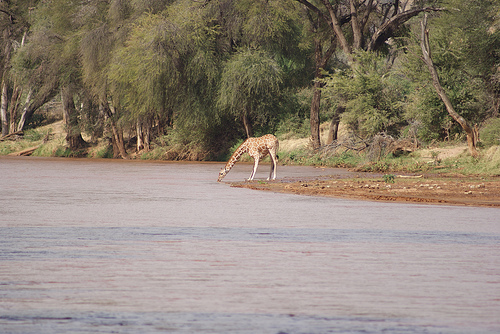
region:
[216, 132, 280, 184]
giraffe drinking at lake edge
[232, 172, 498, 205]
muddy and sandy lake shoreline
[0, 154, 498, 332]
large water source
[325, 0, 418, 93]
tree trunk of very large tree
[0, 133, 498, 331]
solitary giraffe at lake shore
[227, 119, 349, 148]
brown hillside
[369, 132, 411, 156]
large tree stump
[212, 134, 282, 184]
giraffe bends neck down to drink from lake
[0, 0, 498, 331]
giraffe drinking from lake in natural habitat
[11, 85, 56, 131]
that is a tree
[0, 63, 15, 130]
that is a tree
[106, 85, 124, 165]
that is a tree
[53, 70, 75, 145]
that is a tree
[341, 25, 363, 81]
that is a tree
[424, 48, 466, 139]
that is a tree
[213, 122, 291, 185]
that is a giraffe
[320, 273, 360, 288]
this is clean water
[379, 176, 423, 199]
that is a mudy ground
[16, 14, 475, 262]
a giraffe is taking a drink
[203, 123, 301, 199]
this giraffe's neck is bent over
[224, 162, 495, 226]
this is dirt by the water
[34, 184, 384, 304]
the water is light blue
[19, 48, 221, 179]
trees on the shore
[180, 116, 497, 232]
the giraffe is by itself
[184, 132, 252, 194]
the giraffe has a long neck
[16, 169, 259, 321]
the water looks calm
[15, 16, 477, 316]
a scene of a giraffe in the wild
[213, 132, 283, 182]
Giraffe drinking from water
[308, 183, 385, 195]
Dirt area near lake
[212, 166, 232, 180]
Head of spotted giraffe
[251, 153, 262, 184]
Leg of spotted giraffe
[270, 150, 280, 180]
Leg of spotted giraffe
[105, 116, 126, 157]
Tree trunk near edge of water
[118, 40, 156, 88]
Green tree near water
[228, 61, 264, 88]
Green tree near water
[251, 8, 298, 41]
Part of tree near water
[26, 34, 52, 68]
Part of tree near water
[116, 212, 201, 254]
beautiful drinking pond water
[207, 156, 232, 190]
giraffe head looking down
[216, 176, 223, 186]
giraffe mouth in water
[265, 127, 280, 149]
butt of long giraffe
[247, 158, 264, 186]
front legs on giraffe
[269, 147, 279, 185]
back legs on giraffe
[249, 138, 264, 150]
yellow spots on giraffe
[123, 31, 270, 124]
big green bushy trees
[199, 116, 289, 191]
giraffe standing on dirt